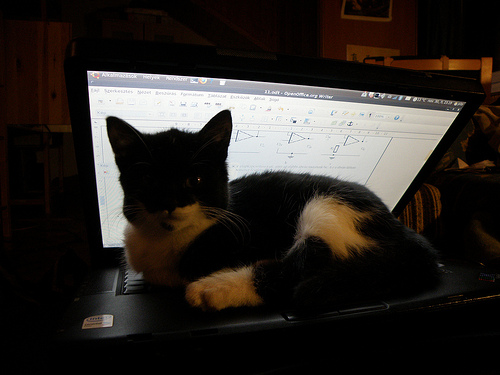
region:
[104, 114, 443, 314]
black and white cat sitting on a lap top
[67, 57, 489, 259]
the lap top screen is partially closed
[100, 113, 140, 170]
the right ear of the cat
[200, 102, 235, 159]
the left ear of the cat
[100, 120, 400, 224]
a software program is open on the screen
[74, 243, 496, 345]
the keyboard of the computer that which the cat is sitting on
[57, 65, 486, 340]
a black intel lap top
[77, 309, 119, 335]
intel symbol sticker on the lap top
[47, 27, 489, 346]
a black PC lap top that is partially closed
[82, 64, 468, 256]
the screen of the lap top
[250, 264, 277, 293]
Long black hair on animal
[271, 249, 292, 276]
Long black hair on animal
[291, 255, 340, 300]
Long black hair on animal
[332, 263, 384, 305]
Long black hair on animal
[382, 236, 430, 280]
Long black hair on animal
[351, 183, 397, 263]
Long black hair on animal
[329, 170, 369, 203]
Long black hair on animal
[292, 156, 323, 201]
Long black hair on animal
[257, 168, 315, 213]
Long black hair on animal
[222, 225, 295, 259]
Long black hair on animal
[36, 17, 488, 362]
cat in a darkened room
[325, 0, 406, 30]
wall hanging in the background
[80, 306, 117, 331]
informational sticker on a laptop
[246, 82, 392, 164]
lit screen of a laptop computer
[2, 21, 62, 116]
varnished wood panels of the wall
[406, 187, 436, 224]
portion of a bedspread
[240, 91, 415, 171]
a computer's software program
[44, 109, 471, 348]
feline laying on a keyboard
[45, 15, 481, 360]
cat on a partially closed laptop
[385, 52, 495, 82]
wood from a piece of furniture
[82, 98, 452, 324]
This is a cat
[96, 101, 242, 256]
Head of a cat